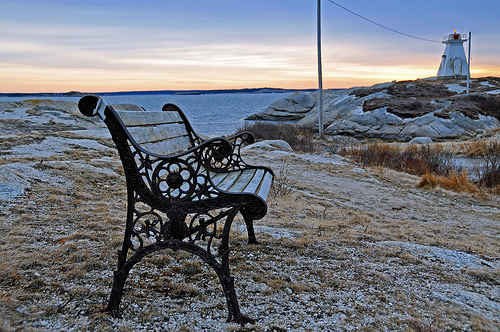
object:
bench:
[76, 94, 274, 325]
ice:
[95, 110, 273, 203]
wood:
[116, 110, 274, 200]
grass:
[319, 208, 376, 237]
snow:
[93, 97, 109, 121]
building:
[436, 30, 470, 79]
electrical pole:
[315, 0, 325, 135]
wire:
[328, 0, 444, 43]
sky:
[1, 0, 500, 95]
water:
[196, 99, 235, 115]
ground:
[0, 151, 500, 331]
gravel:
[289, 287, 346, 323]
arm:
[128, 135, 234, 204]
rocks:
[0, 161, 54, 208]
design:
[120, 137, 237, 269]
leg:
[106, 262, 129, 315]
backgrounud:
[0, 1, 500, 138]